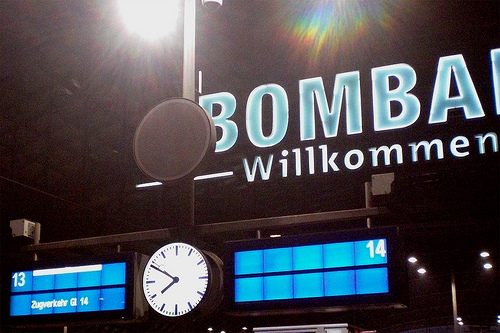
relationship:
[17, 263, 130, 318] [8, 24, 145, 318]
screen on wall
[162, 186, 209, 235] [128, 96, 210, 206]
post has black light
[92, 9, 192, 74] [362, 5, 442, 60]
light on roof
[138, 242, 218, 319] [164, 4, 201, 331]
clock on pole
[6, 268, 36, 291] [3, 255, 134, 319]
13 on blue screen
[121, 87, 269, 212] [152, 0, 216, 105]
speaker on pole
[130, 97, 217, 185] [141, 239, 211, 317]
circle above clock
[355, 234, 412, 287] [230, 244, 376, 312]
14 on squares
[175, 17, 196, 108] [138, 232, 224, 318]
pole supporting clock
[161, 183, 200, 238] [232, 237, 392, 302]
pole supports lights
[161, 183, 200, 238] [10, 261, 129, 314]
pole supports lights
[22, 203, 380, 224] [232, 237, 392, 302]
pole supports lights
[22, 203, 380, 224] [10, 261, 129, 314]
pole supports lights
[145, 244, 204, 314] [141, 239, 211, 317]
numbers on clock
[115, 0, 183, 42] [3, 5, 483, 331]
light shining in building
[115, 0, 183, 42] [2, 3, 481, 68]
light coming from ceiling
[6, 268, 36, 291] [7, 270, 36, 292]
13 on first square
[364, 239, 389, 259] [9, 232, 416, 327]
14 on sign